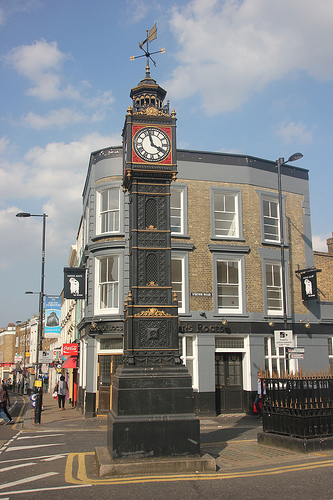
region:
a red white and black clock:
[131, 122, 172, 164]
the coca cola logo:
[63, 343, 79, 353]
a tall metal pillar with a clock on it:
[106, 78, 201, 456]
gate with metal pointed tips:
[258, 363, 331, 437]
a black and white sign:
[63, 267, 83, 297]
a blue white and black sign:
[43, 294, 61, 340]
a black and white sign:
[301, 269, 320, 298]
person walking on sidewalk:
[53, 375, 71, 410]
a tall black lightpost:
[16, 211, 46, 427]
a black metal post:
[32, 376, 41, 423]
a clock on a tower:
[131, 126, 169, 161]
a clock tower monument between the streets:
[93, 22, 217, 474]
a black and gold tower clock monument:
[94, 23, 217, 478]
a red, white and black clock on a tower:
[131, 122, 172, 166]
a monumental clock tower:
[90, 22, 216, 481]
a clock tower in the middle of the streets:
[93, 20, 217, 474]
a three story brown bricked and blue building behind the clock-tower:
[79, 144, 330, 415]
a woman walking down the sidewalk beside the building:
[50, 374, 69, 410]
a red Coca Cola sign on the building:
[61, 343, 78, 356]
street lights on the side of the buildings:
[15, 211, 48, 426]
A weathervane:
[129, 22, 166, 73]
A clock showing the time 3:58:
[128, 114, 175, 168]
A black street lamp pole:
[14, 211, 48, 350]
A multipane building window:
[209, 187, 243, 240]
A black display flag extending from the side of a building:
[61, 265, 97, 300]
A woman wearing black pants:
[51, 375, 70, 411]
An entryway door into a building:
[212, 334, 249, 413]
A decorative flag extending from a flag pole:
[35, 294, 62, 338]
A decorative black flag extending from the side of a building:
[293, 263, 332, 302]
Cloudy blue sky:
[0, 0, 120, 141]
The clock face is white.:
[133, 125, 171, 162]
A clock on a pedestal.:
[93, 23, 217, 479]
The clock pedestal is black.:
[93, 22, 216, 481]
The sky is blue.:
[0, 0, 332, 329]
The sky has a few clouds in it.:
[0, 0, 332, 333]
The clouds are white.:
[0, 0, 331, 329]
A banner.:
[62, 266, 88, 298]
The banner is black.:
[62, 266, 86, 298]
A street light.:
[14, 210, 50, 426]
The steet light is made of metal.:
[13, 209, 51, 424]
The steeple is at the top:
[127, 21, 171, 73]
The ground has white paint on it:
[6, 427, 57, 498]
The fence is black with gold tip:
[250, 366, 331, 442]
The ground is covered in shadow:
[6, 417, 103, 481]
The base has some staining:
[104, 372, 207, 462]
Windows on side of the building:
[185, 180, 304, 308]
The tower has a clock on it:
[124, 88, 181, 188]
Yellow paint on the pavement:
[63, 441, 92, 494]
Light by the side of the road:
[271, 140, 313, 350]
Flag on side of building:
[45, 253, 92, 306]